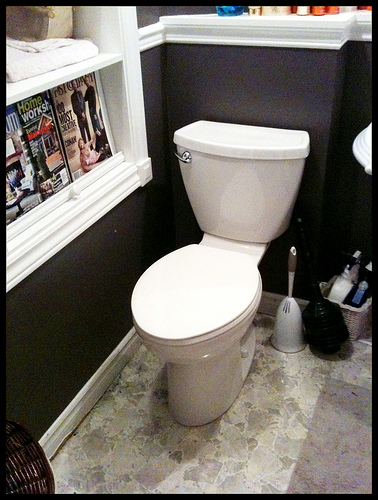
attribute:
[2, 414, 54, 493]
basket — Dark brown wicker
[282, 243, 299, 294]
toilet brush — Toilet cleaning 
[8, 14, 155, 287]
shelf — White 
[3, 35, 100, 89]
towel — White folded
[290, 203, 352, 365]
plunger — Black plastic toilet 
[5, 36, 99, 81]
towel — Folded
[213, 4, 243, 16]
item — Bathroom 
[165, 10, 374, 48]
shelf — Small white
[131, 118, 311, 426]
toilet — behind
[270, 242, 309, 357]
brush —  toilet 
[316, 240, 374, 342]
bathroom — items 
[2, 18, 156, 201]
shelf — built in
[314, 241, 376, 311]
cleaning supplies — Cleaning 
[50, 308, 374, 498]
floor — Linoleum 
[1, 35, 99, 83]
white towel — white 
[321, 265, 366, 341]
basket — wicker 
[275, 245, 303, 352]
brush — Toilet bowl 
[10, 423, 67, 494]
basket — wicker, Edge 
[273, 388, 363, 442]
design — stone 